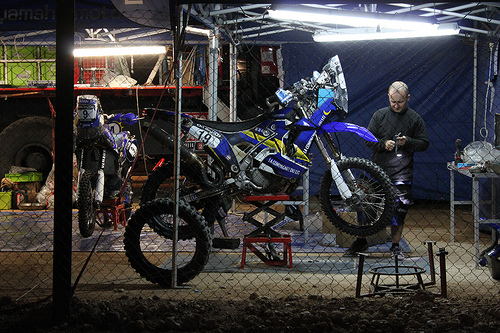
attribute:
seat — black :
[184, 102, 284, 136]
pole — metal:
[46, 2, 86, 317]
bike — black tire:
[111, 62, 459, 272]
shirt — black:
[363, 103, 431, 175]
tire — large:
[311, 144, 403, 239]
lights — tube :
[269, 9, 466, 58]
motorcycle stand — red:
[239, 188, 295, 271]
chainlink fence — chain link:
[0, 7, 499, 308]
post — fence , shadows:
[50, 18, 105, 324]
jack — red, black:
[234, 192, 293, 271]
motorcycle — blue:
[123, 55, 400, 288]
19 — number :
[198, 130, 211, 142]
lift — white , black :
[236, 204, 296, 263]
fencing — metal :
[4, 10, 499, 322]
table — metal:
[447, 159, 498, 266]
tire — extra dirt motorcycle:
[121, 195, 215, 285]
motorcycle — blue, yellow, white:
[131, 51, 398, 238]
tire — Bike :
[317, 160, 397, 240]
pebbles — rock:
[233, 303, 329, 325]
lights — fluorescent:
[258, 2, 452, 54]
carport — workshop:
[2, 0, 499, 301]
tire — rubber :
[73, 142, 107, 239]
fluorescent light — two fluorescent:
[307, 26, 464, 43]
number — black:
[199, 130, 209, 142]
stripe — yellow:
[239, 130, 306, 160]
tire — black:
[124, 197, 209, 284]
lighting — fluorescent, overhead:
[266, 5, 460, 40]